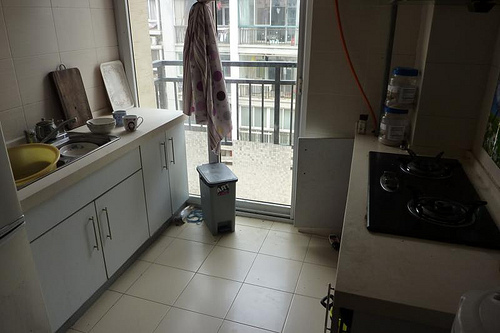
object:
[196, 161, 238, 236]
trash bin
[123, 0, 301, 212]
glass door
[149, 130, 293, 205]
deck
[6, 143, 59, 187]
yellow tub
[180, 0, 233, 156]
towel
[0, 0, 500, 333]
kitchen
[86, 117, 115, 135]
bowl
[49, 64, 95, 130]
cutting board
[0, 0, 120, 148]
wall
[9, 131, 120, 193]
sink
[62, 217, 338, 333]
tiles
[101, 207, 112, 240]
handle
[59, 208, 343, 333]
tile floor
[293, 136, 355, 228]
cabinet door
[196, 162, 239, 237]
can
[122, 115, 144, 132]
mug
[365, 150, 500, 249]
stove top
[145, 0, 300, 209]
glass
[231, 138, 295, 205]
patio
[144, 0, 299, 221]
door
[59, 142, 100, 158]
dishes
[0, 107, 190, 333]
counter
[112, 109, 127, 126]
cup